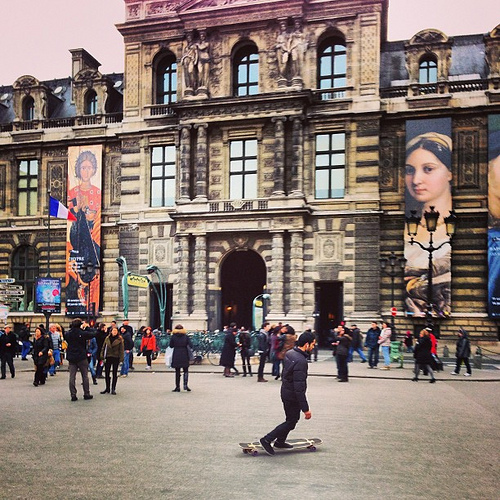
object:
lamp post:
[427, 254, 434, 328]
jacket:
[139, 333, 156, 354]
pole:
[157, 310, 165, 335]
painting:
[64, 142, 103, 319]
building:
[0, 0, 499, 340]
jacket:
[169, 328, 196, 370]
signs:
[0, 277, 17, 284]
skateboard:
[235, 438, 324, 456]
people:
[256, 319, 270, 384]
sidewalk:
[0, 353, 500, 382]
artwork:
[402, 117, 454, 319]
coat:
[429, 332, 439, 357]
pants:
[378, 345, 392, 367]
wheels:
[250, 450, 258, 458]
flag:
[47, 193, 78, 222]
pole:
[47, 188, 51, 281]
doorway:
[212, 245, 269, 336]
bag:
[163, 346, 173, 369]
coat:
[61, 329, 96, 364]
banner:
[485, 113, 499, 317]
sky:
[0, 0, 499, 95]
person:
[168, 322, 197, 392]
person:
[99, 325, 125, 396]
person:
[329, 326, 352, 382]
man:
[258, 330, 316, 457]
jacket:
[279, 346, 312, 414]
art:
[32, 281, 60, 309]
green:
[122, 267, 127, 314]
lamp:
[145, 262, 167, 336]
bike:
[187, 328, 225, 366]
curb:
[10, 367, 500, 384]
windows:
[161, 143, 178, 166]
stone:
[343, 223, 356, 233]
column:
[268, 232, 284, 316]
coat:
[217, 332, 237, 369]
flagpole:
[45, 196, 50, 274]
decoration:
[316, 230, 344, 268]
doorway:
[311, 277, 345, 351]